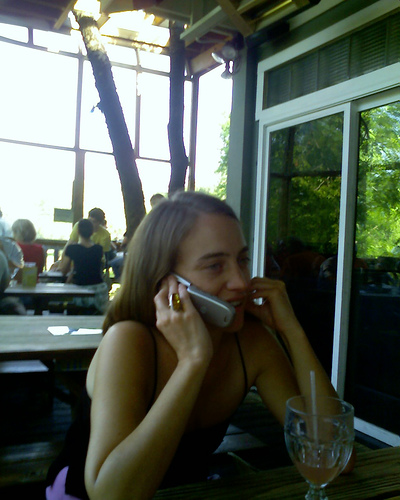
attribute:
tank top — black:
[76, 310, 245, 494]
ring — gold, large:
[168, 292, 179, 308]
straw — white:
[308, 372, 322, 444]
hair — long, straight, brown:
[83, 173, 260, 329]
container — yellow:
[20, 261, 37, 287]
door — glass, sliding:
[265, 89, 394, 442]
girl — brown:
[84, 186, 270, 329]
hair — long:
[152, 192, 218, 272]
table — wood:
[234, 449, 399, 495]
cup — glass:
[282, 393, 354, 499]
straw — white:
[308, 368, 319, 441]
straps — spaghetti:
[147, 328, 160, 398]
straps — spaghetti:
[232, 335, 250, 391]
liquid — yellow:
[294, 454, 344, 486]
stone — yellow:
[168, 293, 180, 316]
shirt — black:
[64, 317, 248, 498]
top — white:
[22, 260, 35, 265]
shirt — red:
[14, 242, 46, 270]